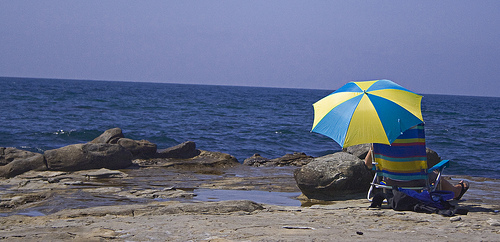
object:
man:
[364, 139, 471, 203]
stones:
[155, 140, 201, 159]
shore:
[0, 127, 500, 241]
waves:
[65, 100, 113, 114]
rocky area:
[0, 127, 500, 241]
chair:
[363, 120, 452, 207]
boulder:
[290, 150, 374, 199]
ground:
[0, 164, 500, 241]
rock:
[99, 126, 127, 145]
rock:
[237, 152, 271, 167]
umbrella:
[308, 78, 429, 149]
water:
[192, 185, 303, 207]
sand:
[0, 165, 500, 242]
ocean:
[0, 75, 500, 178]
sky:
[0, 0, 500, 97]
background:
[0, 0, 500, 241]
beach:
[0, 126, 500, 241]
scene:
[0, 0, 500, 241]